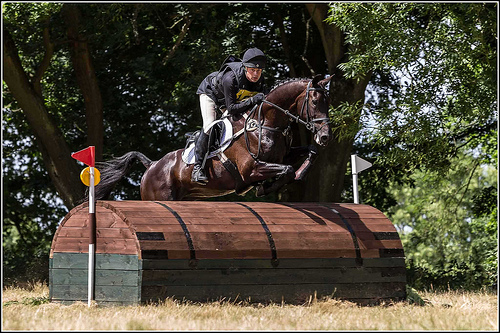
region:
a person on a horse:
[91, 45, 338, 205]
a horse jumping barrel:
[88, 65, 386, 226]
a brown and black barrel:
[13, 172, 413, 328]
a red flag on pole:
[56, 129, 148, 318]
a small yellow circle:
[78, 162, 121, 194]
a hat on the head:
[234, 45, 282, 94]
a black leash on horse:
[233, 85, 339, 161]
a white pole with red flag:
[76, 159, 123, 329]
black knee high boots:
[178, 110, 248, 201]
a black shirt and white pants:
[186, 54, 266, 154]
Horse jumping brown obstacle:
[82, 40, 352, 205]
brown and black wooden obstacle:
[40, 190, 418, 311]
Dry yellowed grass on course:
[0, 298, 348, 328]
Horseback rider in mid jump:
[173, 35, 273, 180]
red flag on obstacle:
[67, 137, 108, 307]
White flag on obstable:
[340, 147, 376, 202]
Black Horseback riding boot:
[182, 121, 219, 191]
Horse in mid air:
[67, 67, 340, 229]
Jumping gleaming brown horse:
[80, 65, 350, 233]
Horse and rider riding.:
[70, 38, 344, 213]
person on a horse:
[91, 33, 347, 203]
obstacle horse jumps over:
[24, 149, 476, 319]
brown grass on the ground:
[6, 289, 485, 329]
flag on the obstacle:
[61, 133, 98, 203]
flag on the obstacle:
[343, 143, 370, 204]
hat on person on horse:
[241, 39, 271, 70]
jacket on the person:
[216, 60, 253, 102]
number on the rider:
[237, 87, 255, 102]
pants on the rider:
[198, 94, 219, 135]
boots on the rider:
[187, 131, 214, 170]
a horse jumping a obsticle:
[153, 49, 338, 277]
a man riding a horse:
[188, 31, 296, 196]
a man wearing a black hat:
[238, 40, 276, 82]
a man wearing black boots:
[190, 123, 230, 171]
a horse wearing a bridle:
[295, 74, 329, 151]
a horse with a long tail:
[94, 142, 168, 192]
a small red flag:
[53, 146, 97, 265]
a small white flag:
[345, 141, 374, 206]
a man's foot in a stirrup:
[183, 155, 214, 189]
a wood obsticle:
[44, 194, 386, 303]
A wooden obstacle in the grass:
[48, 191, 410, 310]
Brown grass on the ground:
[4, 283, 498, 330]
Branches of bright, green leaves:
[3, 3, 498, 290]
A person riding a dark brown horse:
[96, 55, 336, 201]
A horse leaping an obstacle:
[96, 72, 340, 199]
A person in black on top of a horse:
[192, 48, 266, 181]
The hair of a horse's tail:
[87, 149, 155, 200]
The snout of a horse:
[309, 105, 332, 147]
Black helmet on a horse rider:
[242, 47, 267, 68]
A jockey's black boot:
[192, 128, 212, 183]